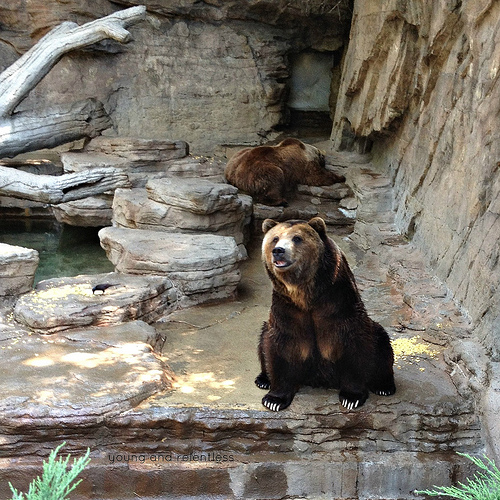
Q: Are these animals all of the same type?
A: No, there are both birds and bears.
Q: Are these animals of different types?
A: Yes, they are birds and bears.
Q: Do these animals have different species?
A: Yes, they are birds and bears.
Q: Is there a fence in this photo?
A: No, there are no fences.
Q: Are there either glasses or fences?
A: No, there are no fences or glasses.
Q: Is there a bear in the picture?
A: Yes, there is a bear.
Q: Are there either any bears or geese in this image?
A: Yes, there is a bear.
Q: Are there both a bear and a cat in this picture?
A: No, there is a bear but no cats.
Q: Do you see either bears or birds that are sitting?
A: Yes, the bear is sitting.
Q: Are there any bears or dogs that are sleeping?
A: Yes, the bear is sleeping.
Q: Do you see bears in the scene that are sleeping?
A: Yes, there is a bear that is sleeping.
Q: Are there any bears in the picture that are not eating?
A: Yes, there is a bear that is sleeping.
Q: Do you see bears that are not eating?
A: Yes, there is a bear that is sleeping .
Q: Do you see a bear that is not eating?
A: Yes, there is a bear that is sleeping .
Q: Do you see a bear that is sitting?
A: Yes, there is a bear that is sitting.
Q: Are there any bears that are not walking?
A: Yes, there is a bear that is sitting.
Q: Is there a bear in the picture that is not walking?
A: Yes, there is a bear that is sitting.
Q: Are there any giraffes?
A: No, there are no giraffes.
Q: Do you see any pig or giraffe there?
A: No, there are no giraffes or pigs.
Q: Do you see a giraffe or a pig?
A: No, there are no giraffes or pigs.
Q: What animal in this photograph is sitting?
A: The animal is a bear.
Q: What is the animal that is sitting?
A: The animal is a bear.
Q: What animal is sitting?
A: The animal is a bear.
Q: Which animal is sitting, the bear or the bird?
A: The bear is sitting.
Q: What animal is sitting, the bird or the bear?
A: The bear is sitting.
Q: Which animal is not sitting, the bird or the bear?
A: The bird is not sitting.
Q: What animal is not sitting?
A: The animal is a bird.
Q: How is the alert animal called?
A: The animal is a bear.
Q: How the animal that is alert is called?
A: The animal is a bear.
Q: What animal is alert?
A: The animal is a bear.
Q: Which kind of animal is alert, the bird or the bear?
A: The bear is alert.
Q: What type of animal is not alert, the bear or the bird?
A: The bird is not alert.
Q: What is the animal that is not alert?
A: The animal is a bird.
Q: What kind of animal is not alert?
A: The animal is a bird.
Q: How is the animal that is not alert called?
A: The animal is a bird.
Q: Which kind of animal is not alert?
A: The animal is a bird.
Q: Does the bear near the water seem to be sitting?
A: Yes, the bear is sitting.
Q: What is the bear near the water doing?
A: The bear is sitting.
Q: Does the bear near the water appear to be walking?
A: No, the bear is sitting.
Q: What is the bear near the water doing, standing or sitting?
A: The bear is sitting.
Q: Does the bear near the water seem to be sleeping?
A: Yes, the bear is sleeping.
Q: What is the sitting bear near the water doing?
A: The bear is sleeping.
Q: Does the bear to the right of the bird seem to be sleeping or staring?
A: The bear is sleeping.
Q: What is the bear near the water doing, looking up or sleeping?
A: The bear is sleeping.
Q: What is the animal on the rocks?
A: The animal is a bear.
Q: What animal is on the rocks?
A: The animal is a bear.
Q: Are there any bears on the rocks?
A: Yes, there is a bear on the rocks.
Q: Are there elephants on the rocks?
A: No, there is a bear on the rocks.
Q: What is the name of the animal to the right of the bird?
A: The animal is a bear.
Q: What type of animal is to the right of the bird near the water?
A: The animal is a bear.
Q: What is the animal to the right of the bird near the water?
A: The animal is a bear.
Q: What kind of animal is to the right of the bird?
A: The animal is a bear.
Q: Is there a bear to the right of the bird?
A: Yes, there is a bear to the right of the bird.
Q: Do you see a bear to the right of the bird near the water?
A: Yes, there is a bear to the right of the bird.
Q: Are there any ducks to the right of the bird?
A: No, there is a bear to the right of the bird.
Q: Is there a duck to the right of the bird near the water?
A: No, there is a bear to the right of the bird.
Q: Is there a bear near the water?
A: Yes, there is a bear near the water.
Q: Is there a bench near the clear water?
A: No, there is a bear near the water.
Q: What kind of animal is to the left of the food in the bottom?
A: The animal is a bear.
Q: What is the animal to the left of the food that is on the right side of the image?
A: The animal is a bear.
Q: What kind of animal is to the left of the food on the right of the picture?
A: The animal is a bear.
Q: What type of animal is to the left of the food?
A: The animal is a bear.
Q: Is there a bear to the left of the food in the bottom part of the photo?
A: Yes, there is a bear to the left of the food.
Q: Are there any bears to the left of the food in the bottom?
A: Yes, there is a bear to the left of the food.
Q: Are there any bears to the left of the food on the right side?
A: Yes, there is a bear to the left of the food.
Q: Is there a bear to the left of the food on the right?
A: Yes, there is a bear to the left of the food.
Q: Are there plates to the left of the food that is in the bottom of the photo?
A: No, there is a bear to the left of the food.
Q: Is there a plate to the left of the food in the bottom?
A: No, there is a bear to the left of the food.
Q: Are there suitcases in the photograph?
A: No, there are no suitcases.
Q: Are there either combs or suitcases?
A: No, there are no suitcases or combs.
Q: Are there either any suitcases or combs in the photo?
A: No, there are no suitcases or combs.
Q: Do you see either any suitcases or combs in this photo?
A: No, there are no suitcases or combs.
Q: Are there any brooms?
A: No, there are no brooms.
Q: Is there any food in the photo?
A: Yes, there is food.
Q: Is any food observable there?
A: Yes, there is food.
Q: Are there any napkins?
A: No, there are no napkins.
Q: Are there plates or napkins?
A: No, there are no napkins or plates.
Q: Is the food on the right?
A: Yes, the food is on the right of the image.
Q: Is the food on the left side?
A: No, the food is on the right of the image.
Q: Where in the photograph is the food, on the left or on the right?
A: The food is on the right of the image.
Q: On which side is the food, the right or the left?
A: The food is on the right of the image.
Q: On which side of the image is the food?
A: The food is on the right of the image.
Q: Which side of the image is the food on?
A: The food is on the right of the image.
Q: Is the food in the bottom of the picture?
A: Yes, the food is in the bottom of the image.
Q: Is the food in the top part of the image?
A: No, the food is in the bottom of the image.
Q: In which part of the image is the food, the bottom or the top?
A: The food is in the bottom of the image.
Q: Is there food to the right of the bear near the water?
A: Yes, there is food to the right of the bear.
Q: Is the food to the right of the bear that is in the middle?
A: Yes, the food is to the right of the bear.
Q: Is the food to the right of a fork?
A: No, the food is to the right of the bear.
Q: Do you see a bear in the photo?
A: Yes, there is a bear.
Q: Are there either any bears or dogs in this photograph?
A: Yes, there is a bear.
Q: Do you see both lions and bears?
A: No, there is a bear but no lions.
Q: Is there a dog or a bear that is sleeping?
A: Yes, the bear is sleeping.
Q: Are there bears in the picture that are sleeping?
A: Yes, there is a bear that is sleeping.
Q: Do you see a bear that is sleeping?
A: Yes, there is a bear that is sleeping.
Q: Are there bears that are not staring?
A: Yes, there is a bear that is sleeping.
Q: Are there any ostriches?
A: No, there are no ostriches.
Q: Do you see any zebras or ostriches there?
A: No, there are no ostriches or zebras.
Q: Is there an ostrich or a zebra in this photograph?
A: No, there are no ostriches or zebras.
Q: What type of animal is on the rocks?
A: The animal is a bear.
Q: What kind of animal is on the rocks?
A: The animal is a bear.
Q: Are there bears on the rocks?
A: Yes, there is a bear on the rocks.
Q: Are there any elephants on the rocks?
A: No, there is a bear on the rocks.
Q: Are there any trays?
A: No, there are no trays.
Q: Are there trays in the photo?
A: No, there are no trays.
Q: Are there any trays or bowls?
A: No, there are no trays or bowls.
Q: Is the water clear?
A: Yes, the water is clear.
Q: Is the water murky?
A: No, the water is clear.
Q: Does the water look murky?
A: No, the water is clear.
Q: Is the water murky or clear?
A: The water is clear.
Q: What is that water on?
A: The water is on the rocks.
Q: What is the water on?
A: The water is on the rocks.